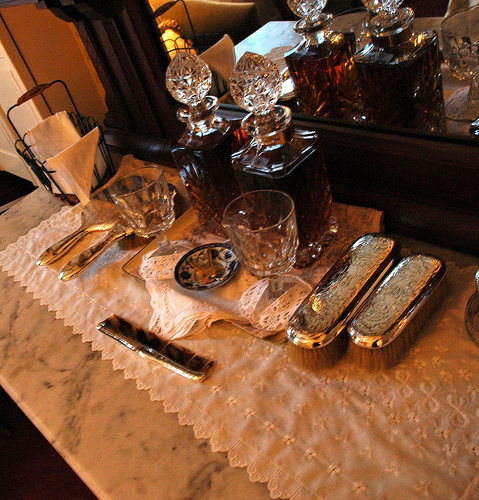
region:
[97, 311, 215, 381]
Comb on white napkin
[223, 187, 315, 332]
Glass cup next to brush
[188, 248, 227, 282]
pair of keys in small dish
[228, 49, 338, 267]
Large whiskey bottle against mirror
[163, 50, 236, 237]
Large whiskey bottle against mirror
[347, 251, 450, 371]
Brush next to big brush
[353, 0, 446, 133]
Reflection of whiskey bottle in mirror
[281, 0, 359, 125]
Reflection of whiskey bottle in mirror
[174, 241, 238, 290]
Small blue and white dish in front of whiskey bottle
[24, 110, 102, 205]
White napkin on black basket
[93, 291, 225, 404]
a comb on the dresser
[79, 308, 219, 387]
the comb is silver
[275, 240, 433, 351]
brushes on the dresser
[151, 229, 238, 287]
a saucer on the dresser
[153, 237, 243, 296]
the saucer has keys in it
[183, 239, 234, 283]
the keys are gold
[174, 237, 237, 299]
the saucer is blue and white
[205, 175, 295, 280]
a glass cup on the dresser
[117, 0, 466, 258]
a mirror on the dresser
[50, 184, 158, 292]
a brush with a handle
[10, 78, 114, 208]
metal framed basket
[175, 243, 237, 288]
small white and blue dish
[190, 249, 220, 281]
a pair of gold keys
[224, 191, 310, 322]
clear glass infront of scotch bottle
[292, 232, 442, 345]
silver backs on scrub brushes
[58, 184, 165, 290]
hair brush with silver handle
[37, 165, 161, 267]
a hand mirror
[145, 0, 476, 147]
reflection of items on table in mirror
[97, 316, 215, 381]
a gold and black comb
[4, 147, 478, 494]
white placement cloth on desk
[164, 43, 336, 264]
glass bottles of scotch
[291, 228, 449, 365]
silver handle brushes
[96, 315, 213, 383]
a gold metal comb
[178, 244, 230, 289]
a small round dish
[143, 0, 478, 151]
mirror with wood frame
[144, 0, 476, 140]
reflection of glass bottles in mirror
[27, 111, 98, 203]
white folded cloth in basket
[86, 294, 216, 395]
comb on front of napkin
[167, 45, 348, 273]
two bottles with toppers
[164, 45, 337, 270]
alcohol in two bottles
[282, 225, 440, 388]
two rectangluar brushes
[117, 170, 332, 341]
two glasses with stems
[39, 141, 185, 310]
two brushes on the left of glass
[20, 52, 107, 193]
basket next to brushes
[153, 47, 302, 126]
bottle toppers are glass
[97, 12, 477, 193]
mirror behind bottles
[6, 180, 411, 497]
marble top on the dresser